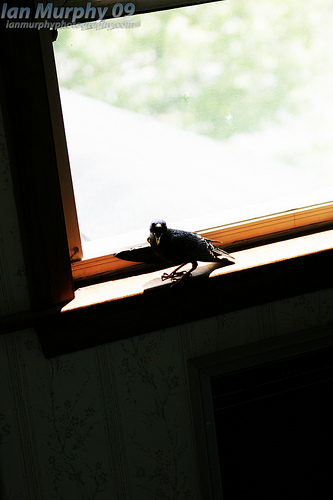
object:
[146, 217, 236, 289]
bird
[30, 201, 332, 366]
sill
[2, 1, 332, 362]
window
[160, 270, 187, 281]
foot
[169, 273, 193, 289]
foot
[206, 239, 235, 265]
tail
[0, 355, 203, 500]
wallpaper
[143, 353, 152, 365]
flower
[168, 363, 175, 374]
flower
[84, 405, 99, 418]
flower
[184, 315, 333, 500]
vent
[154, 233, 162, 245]
beak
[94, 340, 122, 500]
line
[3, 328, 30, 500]
line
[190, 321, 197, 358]
line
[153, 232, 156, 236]
eye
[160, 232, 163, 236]
eye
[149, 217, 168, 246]
head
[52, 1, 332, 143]
vegetation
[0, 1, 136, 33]
wording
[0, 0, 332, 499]
wall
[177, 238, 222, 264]
wing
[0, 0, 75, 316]
frame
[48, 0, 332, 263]
view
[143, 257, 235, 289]
shadow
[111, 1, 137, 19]
09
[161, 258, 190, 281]
leg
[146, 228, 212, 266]
body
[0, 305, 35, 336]
chair rail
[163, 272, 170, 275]
talon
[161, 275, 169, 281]
talon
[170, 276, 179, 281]
talon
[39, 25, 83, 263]
frame